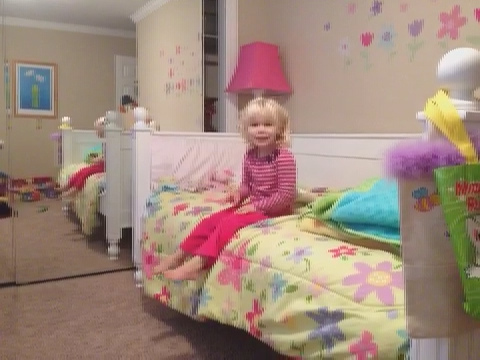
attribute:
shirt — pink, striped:
[227, 142, 300, 222]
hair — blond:
[230, 92, 305, 154]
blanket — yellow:
[135, 168, 416, 358]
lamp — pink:
[226, 32, 297, 135]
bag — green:
[423, 153, 479, 325]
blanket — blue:
[301, 163, 425, 261]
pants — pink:
[187, 212, 281, 260]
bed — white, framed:
[98, 117, 443, 357]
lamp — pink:
[218, 48, 300, 125]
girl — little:
[148, 97, 330, 279]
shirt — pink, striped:
[236, 133, 301, 208]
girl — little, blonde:
[134, 86, 305, 295]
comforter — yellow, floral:
[151, 184, 431, 355]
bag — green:
[423, 108, 479, 330]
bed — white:
[119, 130, 479, 344]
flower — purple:
[394, 19, 435, 75]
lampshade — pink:
[223, 34, 299, 108]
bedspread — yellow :
[149, 177, 419, 358]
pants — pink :
[172, 202, 269, 261]